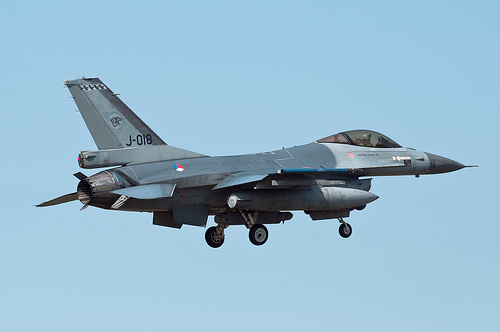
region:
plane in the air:
[4, 63, 412, 248]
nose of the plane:
[422, 150, 479, 186]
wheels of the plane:
[161, 225, 352, 259]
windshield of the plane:
[330, 118, 420, 148]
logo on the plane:
[164, 157, 190, 176]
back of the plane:
[74, 180, 131, 216]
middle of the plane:
[217, 145, 271, 185]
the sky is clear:
[65, 266, 210, 316]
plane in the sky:
[31, 56, 494, 239]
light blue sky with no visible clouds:
[1, 0, 499, 330]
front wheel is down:
[331, 215, 361, 242]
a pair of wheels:
[198, 219, 278, 251]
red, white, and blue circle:
[168, 161, 190, 175]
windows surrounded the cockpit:
[312, 115, 409, 157]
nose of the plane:
[422, 141, 483, 185]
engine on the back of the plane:
[61, 171, 127, 213]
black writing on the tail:
[121, 131, 159, 145]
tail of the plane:
[29, 73, 191, 253]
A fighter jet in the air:
[29, 65, 486, 253]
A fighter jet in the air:
[33, 70, 482, 253]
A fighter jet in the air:
[28, 71, 485, 251]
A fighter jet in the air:
[26, 70, 486, 255]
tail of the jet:
[65, 75, 160, 145]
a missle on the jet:
[320, 178, 385, 209]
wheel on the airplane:
[245, 224, 278, 246]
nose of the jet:
[439, 147, 482, 180]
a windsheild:
[348, 127, 394, 144]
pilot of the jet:
[357, 129, 376, 145]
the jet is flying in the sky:
[41, 70, 495, 248]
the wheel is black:
[203, 229, 233, 251]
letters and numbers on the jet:
[122, 132, 157, 149]